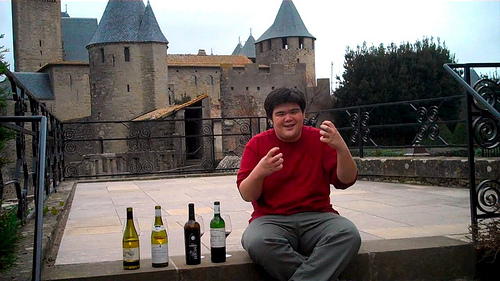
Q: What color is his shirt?
A: Red.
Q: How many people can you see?
A: 1.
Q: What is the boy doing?
A: Smiling.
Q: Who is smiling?
A: The boy.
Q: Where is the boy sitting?
A: On the step.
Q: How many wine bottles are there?
A: 4.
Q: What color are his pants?
A: Grey.